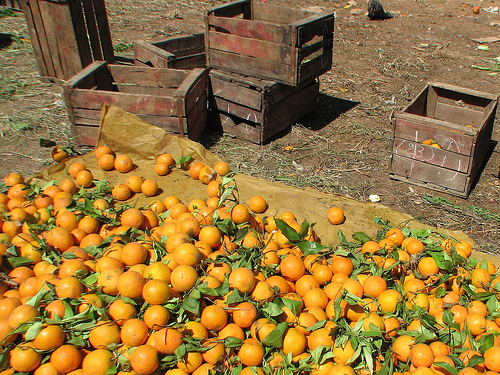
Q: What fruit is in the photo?
A: Oranges.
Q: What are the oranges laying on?
A: Brown paper.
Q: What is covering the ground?
A: Dirt.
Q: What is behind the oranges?
A: Crates.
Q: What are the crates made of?
A: Wood.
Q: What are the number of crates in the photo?
A: Six.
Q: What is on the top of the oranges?
A: Leaves.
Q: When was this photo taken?
A: In the daytime.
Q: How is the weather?
A: Sunny.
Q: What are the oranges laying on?
A: Brown paper.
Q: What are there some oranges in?
A: Crate.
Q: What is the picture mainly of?
A: Oranges.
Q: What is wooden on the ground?
A: Crates.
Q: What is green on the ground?
A: Grass.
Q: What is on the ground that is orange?
A: Oranges.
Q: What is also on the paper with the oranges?
A: Leaves.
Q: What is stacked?
A: Crates.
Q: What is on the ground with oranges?
A: Crate.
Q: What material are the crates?
A: Wood.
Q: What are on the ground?
A: Oranges.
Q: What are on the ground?
A: Oranges.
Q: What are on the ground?
A: Oranges.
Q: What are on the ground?
A: Oranges.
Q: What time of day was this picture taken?
A: Daytime.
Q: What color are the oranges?
A: Orange.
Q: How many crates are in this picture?
A: Six.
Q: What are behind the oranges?
A: Crates.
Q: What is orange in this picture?
A: Oranges.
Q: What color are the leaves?
A: Green.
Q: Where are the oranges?
A: On the ground.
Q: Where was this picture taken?
A: On a farm.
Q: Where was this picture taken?
A: Fruit farm.